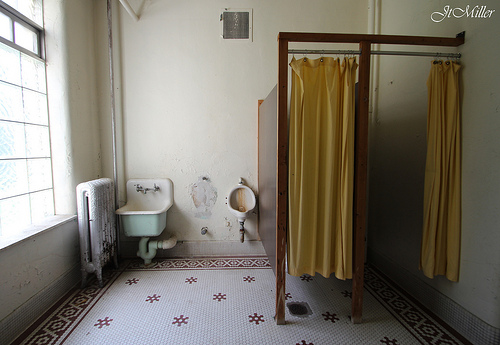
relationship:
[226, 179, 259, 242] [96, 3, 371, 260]
urinal on wall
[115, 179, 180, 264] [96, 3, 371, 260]
sink on wall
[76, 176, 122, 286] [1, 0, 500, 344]
radiator in bathroom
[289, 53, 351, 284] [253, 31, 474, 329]
curtain on stall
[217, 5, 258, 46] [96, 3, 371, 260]
vent on wall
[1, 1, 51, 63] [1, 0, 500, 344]
window in bathroom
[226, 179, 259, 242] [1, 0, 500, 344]
urinal in bathroom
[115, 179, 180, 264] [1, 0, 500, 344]
sink in bathroom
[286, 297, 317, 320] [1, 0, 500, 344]
drain on floor in bathroom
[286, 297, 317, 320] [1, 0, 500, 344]
drain in bathroom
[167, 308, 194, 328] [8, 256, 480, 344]
design on tile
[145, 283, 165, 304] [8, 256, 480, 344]
design on tile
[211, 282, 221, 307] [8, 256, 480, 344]
design on tile